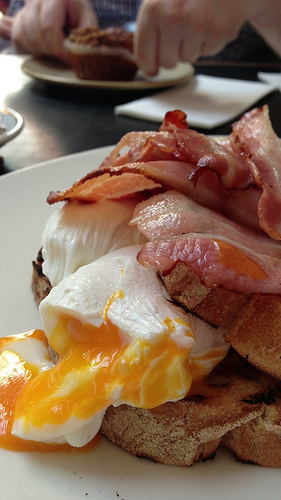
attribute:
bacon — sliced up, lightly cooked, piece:
[47, 105, 280, 288]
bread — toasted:
[156, 254, 279, 378]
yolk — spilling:
[1, 335, 186, 452]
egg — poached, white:
[3, 202, 227, 455]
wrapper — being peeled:
[62, 41, 140, 80]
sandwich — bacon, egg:
[1, 106, 279, 472]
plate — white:
[1, 134, 278, 498]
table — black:
[2, 53, 279, 171]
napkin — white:
[115, 72, 278, 128]